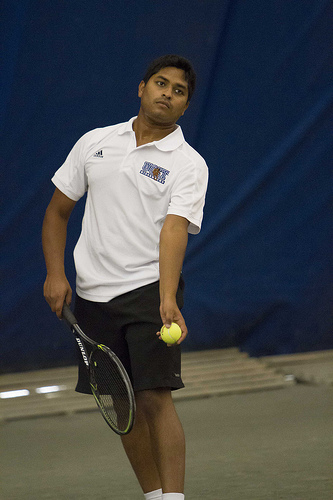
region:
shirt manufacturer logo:
[87, 144, 105, 159]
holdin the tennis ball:
[156, 308, 185, 345]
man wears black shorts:
[63, 288, 188, 393]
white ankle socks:
[135, 486, 187, 499]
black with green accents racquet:
[60, 292, 135, 435]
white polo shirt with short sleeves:
[50, 118, 209, 302]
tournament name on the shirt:
[132, 149, 172, 188]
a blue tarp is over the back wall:
[0, 0, 327, 348]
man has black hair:
[127, 52, 205, 128]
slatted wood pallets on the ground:
[0, 347, 298, 426]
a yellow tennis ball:
[153, 318, 186, 344]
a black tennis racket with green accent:
[63, 313, 134, 442]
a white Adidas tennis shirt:
[45, 116, 208, 296]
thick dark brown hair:
[141, 50, 193, 77]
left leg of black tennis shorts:
[126, 350, 188, 393]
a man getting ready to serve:
[45, 53, 195, 439]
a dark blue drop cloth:
[218, 59, 318, 346]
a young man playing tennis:
[60, 53, 220, 487]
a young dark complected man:
[129, 51, 198, 129]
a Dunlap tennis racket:
[56, 304, 137, 441]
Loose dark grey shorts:
[73, 271, 185, 393]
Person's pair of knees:
[108, 386, 176, 420]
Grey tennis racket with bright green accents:
[58, 300, 135, 436]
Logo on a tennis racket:
[73, 335, 88, 368]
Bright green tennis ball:
[160, 321, 182, 345]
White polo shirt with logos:
[49, 113, 209, 303]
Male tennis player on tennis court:
[39, 53, 216, 499]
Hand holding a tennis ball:
[155, 302, 188, 348]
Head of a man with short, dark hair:
[134, 56, 196, 124]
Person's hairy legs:
[82, 339, 188, 498]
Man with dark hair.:
[99, 40, 260, 172]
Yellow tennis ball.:
[152, 312, 220, 370]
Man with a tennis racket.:
[23, 275, 158, 443]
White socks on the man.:
[136, 488, 187, 498]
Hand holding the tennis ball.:
[141, 302, 207, 355]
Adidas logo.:
[83, 137, 115, 168]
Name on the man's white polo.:
[134, 146, 186, 203]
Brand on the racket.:
[63, 324, 95, 383]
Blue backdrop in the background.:
[207, 182, 309, 359]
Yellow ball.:
[151, 316, 202, 354]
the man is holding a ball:
[155, 303, 188, 347]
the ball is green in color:
[161, 321, 180, 340]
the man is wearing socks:
[138, 486, 184, 498]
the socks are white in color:
[140, 491, 186, 499]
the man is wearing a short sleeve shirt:
[53, 114, 208, 305]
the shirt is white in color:
[52, 115, 209, 306]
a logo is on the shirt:
[92, 148, 105, 158]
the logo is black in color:
[92, 150, 105, 159]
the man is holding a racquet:
[42, 279, 139, 431]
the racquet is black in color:
[46, 291, 139, 438]